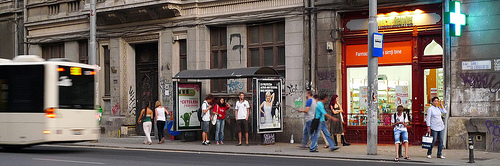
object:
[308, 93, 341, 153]
man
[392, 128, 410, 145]
blue jeans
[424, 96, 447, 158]
woman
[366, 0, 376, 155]
pole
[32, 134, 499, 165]
sidewalk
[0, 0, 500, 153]
building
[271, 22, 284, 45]
window